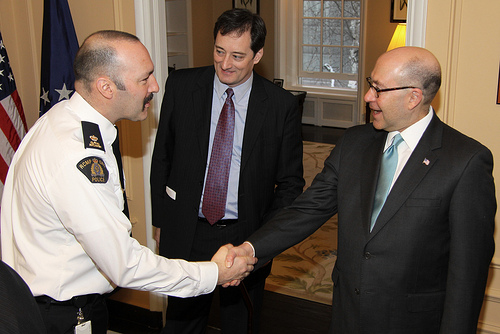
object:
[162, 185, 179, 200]
pamphlet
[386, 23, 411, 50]
lamp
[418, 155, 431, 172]
pin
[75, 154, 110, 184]
badge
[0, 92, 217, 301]
shirt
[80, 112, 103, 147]
isignia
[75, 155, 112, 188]
isignia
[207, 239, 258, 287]
hands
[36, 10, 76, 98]
flag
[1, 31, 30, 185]
flag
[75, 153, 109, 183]
patch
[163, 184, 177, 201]
white paper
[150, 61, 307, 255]
jacket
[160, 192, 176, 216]
pocket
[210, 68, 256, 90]
neck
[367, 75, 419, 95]
black glasses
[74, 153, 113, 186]
elephant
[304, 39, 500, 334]
man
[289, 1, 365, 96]
window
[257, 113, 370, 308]
rug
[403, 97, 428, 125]
ground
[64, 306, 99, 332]
name tag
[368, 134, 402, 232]
blue tie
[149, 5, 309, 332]
man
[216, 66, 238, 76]
smile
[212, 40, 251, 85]
face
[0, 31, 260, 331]
male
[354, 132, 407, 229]
tie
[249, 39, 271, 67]
ear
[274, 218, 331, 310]
rug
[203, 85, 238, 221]
tie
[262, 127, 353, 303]
floor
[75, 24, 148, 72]
baldness